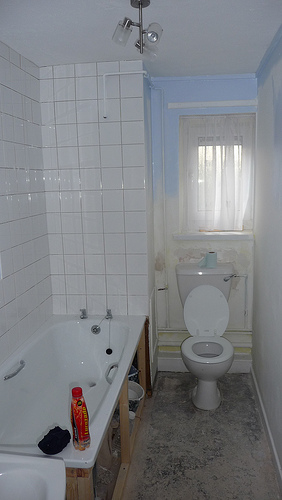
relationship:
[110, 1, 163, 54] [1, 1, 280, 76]
light on ceiling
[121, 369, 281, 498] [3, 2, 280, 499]
floor in bathroom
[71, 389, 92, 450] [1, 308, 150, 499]
bottle on tub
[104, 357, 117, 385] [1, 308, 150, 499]
handle on tub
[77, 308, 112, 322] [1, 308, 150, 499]
faucet on tub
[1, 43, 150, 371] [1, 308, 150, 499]
tile around tub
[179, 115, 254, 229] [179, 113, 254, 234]
curtain in window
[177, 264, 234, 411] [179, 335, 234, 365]
toilet has seat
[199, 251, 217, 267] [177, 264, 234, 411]
paper on toilet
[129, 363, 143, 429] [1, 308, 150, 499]
buckets under tub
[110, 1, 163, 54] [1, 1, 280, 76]
light hanging from ceiling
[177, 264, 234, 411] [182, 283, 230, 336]
toilet has lid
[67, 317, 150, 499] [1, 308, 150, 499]
poles on tub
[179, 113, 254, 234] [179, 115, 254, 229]
window has curtain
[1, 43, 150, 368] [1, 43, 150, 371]
wall has tile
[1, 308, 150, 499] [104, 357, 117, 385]
tub has handle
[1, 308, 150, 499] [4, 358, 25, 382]
tub has handle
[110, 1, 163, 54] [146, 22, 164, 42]
light has light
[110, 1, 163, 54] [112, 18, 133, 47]
light has light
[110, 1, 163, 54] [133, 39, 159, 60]
light has light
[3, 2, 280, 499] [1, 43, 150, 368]
bathroom has wall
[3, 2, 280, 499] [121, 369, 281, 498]
bathroom has floor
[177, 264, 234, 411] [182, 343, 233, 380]
toilet has bowl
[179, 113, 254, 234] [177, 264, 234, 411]
window above toilet